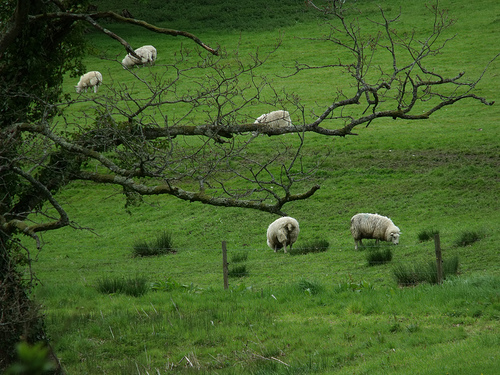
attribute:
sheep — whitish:
[345, 210, 403, 253]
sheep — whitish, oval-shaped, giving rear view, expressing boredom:
[261, 214, 304, 255]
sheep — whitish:
[116, 43, 160, 72]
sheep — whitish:
[72, 66, 106, 98]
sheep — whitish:
[252, 105, 293, 139]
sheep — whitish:
[140, 41, 161, 59]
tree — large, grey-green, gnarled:
[0, 3, 95, 374]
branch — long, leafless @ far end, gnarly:
[2, 5, 230, 67]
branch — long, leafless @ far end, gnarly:
[0, 168, 336, 214]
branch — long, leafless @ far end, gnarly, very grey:
[0, 2, 500, 239]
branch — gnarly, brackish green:
[6, 164, 109, 259]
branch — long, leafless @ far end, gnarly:
[1, 40, 293, 179]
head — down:
[387, 226, 404, 247]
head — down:
[264, 241, 280, 254]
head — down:
[73, 84, 86, 96]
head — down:
[120, 58, 131, 74]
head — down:
[249, 127, 260, 139]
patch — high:
[131, 226, 180, 261]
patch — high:
[92, 270, 146, 300]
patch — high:
[387, 256, 459, 289]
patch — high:
[364, 248, 393, 263]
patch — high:
[287, 237, 331, 256]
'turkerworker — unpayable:
[149, 53, 155, 60]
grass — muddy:
[28, 131, 500, 198]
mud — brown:
[367, 141, 500, 170]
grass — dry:
[39, 291, 307, 374]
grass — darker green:
[92, 270, 148, 302]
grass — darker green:
[128, 226, 180, 261]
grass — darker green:
[220, 242, 250, 286]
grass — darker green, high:
[280, 228, 333, 259]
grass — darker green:
[356, 238, 394, 271]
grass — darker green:
[416, 226, 483, 252]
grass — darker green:
[384, 250, 465, 294]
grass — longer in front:
[2, 249, 498, 373]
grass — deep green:
[2, 1, 395, 47]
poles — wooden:
[215, 230, 445, 293]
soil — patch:
[65, 136, 499, 198]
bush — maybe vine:
[0, 109, 182, 254]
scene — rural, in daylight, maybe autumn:
[0, 1, 500, 374]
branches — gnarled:
[1, 0, 499, 278]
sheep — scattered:
[72, 32, 410, 263]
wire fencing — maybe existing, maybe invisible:
[22, 242, 500, 285]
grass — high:
[273, 274, 373, 302]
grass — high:
[84, 226, 183, 302]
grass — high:
[445, 220, 494, 255]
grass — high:
[38, 287, 148, 324]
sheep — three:
[59, 39, 298, 143]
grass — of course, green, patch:
[4, 3, 497, 365]